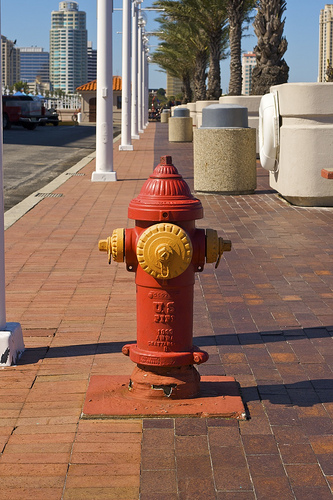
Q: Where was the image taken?
A: It was taken at the sidewalk.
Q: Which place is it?
A: It is a sidewalk.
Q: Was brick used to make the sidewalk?
A: Yes, the sidewalk is made of brick.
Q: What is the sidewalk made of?
A: The sidewalk is made of brick.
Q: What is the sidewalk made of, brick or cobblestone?
A: The sidewalk is made of brick.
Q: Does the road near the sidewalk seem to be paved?
A: Yes, the road is paved.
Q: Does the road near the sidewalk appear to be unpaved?
A: No, the road is paved.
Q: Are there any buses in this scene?
A: No, there are no buses.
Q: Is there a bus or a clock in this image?
A: No, there are no buses or clocks.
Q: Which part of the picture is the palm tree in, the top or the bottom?
A: The palm tree is in the top of the image.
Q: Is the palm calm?
A: Yes, the palm is calm.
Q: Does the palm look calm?
A: Yes, the palm is calm.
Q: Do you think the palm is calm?
A: Yes, the palm is calm.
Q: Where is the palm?
A: The palm is on the side walk.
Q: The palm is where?
A: The palm is on the side walk.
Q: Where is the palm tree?
A: The palm is on the side walk.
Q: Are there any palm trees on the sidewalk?
A: Yes, there is a palm tree on the sidewalk.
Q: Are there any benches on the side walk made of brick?
A: No, there is a palm tree on the sidewalk.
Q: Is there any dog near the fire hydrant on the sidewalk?
A: No, there is a palm tree near the hydrant.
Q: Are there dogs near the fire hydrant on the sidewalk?
A: No, there is a palm tree near the hydrant.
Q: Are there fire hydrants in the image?
A: Yes, there is a fire hydrant.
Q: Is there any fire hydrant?
A: Yes, there is a fire hydrant.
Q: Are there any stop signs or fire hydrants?
A: Yes, there is a fire hydrant.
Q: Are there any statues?
A: No, there are no statues.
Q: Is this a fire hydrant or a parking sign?
A: This is a fire hydrant.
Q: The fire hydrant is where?
A: The fire hydrant is on the sidewalk.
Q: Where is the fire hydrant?
A: The fire hydrant is on the sidewalk.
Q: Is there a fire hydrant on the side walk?
A: Yes, there is a fire hydrant on the side walk.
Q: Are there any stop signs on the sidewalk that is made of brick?
A: No, there is a fire hydrant on the sidewalk.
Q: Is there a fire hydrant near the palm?
A: Yes, there is a fire hydrant near the palm.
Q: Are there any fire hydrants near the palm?
A: Yes, there is a fire hydrant near the palm.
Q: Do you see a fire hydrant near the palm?
A: Yes, there is a fire hydrant near the palm.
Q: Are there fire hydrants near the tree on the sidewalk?
A: Yes, there is a fire hydrant near the palm.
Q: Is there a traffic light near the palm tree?
A: No, there is a fire hydrant near the palm tree.